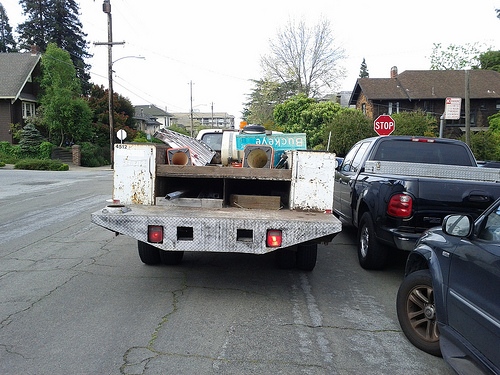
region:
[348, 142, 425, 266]
pick up truck parked on street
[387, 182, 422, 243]
red brake light of truck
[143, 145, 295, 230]
white utility truck stopped on street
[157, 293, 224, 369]
cracks in gray asphalt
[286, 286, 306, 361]
weathered lines on street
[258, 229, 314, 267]
red brake light of utility truck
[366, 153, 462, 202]
gray work box on trucks bed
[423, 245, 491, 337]
dark blue car at curb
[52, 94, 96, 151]
small green leafy tree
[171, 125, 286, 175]
orange safety cones on truck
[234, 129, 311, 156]
Upside down blue street sign that says Buckeye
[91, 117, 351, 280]
Pick up truck carrying a ladder, cones and a street sign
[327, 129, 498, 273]
A black pick up truck parked on the side of the street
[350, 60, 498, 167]
A brown house with a dark brown roof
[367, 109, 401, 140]
Red and white stop sign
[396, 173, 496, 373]
Front end of a gray car parked on the side of the street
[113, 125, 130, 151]
Stop sign seen from the back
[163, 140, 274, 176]
Two traffic cones laying on their sides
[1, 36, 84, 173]
House partially covered with bushes and trees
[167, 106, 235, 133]
Top of a brown and white building in the distance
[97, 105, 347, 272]
a truck on the road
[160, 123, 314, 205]
materials on the truck bed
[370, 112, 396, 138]
a red stop sign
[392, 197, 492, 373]
this car is blue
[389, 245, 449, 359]
the car wheel is turned out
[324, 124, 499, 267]
the pickup is at the stop sign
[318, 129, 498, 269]
the pickup is black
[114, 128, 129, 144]
the back of a stop sign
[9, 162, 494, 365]
the pavement is asphalt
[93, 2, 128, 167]
a tall telephone pole by the street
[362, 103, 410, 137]
a red and white stop sign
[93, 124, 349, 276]
a white work truck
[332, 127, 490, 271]
a truck with a toolbox on the back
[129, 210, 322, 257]
tail lights on a truck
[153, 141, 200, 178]
a orange safety cone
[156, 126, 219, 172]
a metal ladder in the back of a truck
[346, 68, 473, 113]
a house with a shingled roof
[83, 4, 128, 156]
a wood electrical pole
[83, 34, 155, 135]
a street lamp on a pole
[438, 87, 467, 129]
a red and white road sign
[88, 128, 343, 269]
the back of a city truck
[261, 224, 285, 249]
the tail light of a city truck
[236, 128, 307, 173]
a green and white Buckeye sign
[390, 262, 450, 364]
the front tire of a car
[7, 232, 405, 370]
a cracked city street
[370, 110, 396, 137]
a red and white stop sign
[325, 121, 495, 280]
a truck parked on the street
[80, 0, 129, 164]
a wooden telephone pole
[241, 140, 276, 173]
an orange cone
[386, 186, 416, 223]
the tail light on a pickup truck